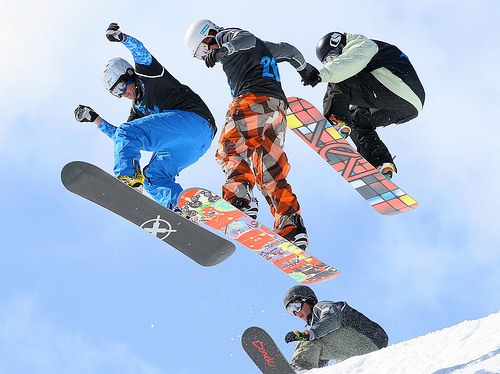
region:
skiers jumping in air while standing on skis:
[56, 14, 435, 370]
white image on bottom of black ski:
[132, 212, 182, 243]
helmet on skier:
[178, 15, 227, 60]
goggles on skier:
[185, 36, 215, 65]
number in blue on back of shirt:
[253, 51, 283, 86]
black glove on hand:
[100, 17, 127, 43]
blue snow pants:
[107, 109, 217, 211]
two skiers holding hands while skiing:
[182, 7, 454, 287]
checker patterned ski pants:
[216, 92, 308, 225]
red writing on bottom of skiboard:
[249, 332, 279, 368]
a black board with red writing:
[240, 326, 301, 372]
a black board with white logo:
[62, 160, 236, 268]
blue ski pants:
[108, 110, 222, 207]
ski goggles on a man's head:
[285, 293, 312, 313]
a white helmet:
[185, 13, 222, 63]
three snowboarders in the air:
[56, 14, 439, 281]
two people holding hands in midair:
[280, 37, 343, 94]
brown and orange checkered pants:
[212, 95, 304, 240]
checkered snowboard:
[290, 98, 411, 215]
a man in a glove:
[282, 329, 312, 341]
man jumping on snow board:
[62, 19, 182, 252]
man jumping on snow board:
[217, 286, 357, 372]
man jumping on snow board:
[200, 24, 294, 267]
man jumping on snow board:
[307, 30, 434, 197]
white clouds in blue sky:
[387, 258, 427, 285]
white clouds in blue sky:
[97, 323, 154, 349]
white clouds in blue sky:
[146, 301, 188, 331]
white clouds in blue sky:
[37, 273, 77, 309]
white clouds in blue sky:
[77, 263, 139, 314]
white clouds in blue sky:
[433, 2, 495, 53]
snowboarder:
[68, 6, 179, 236]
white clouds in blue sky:
[412, 192, 460, 227]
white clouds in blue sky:
[351, 236, 408, 278]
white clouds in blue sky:
[84, 252, 121, 307]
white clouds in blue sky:
[47, 252, 99, 317]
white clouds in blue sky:
[432, 26, 492, 86]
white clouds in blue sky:
[31, 23, 81, 77]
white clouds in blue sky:
[22, 216, 89, 281]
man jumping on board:
[271, 21, 418, 212]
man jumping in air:
[235, 273, 387, 354]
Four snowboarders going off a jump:
[59, 17, 427, 372]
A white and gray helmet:
[98, 55, 136, 91]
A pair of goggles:
[284, 294, 314, 316]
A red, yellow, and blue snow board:
[278, 94, 419, 216]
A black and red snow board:
[239, 324, 297, 371]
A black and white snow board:
[60, 160, 237, 269]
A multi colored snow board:
[175, 185, 342, 285]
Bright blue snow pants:
[110, 108, 216, 215]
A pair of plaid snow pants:
[213, 91, 310, 241]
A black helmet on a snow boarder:
[314, 30, 348, 64]